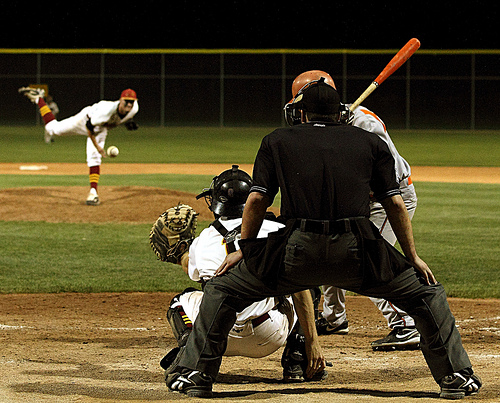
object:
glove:
[150, 202, 195, 264]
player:
[150, 164, 323, 382]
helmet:
[208, 167, 255, 218]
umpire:
[165, 369, 214, 394]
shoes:
[434, 369, 481, 400]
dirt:
[0, 289, 499, 402]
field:
[3, 124, 496, 402]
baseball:
[2, 2, 498, 399]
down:
[148, 322, 357, 395]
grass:
[2, 121, 499, 297]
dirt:
[2, 186, 281, 221]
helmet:
[280, 69, 340, 111]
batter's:
[282, 36, 424, 350]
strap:
[212, 216, 246, 254]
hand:
[302, 337, 326, 378]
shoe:
[282, 342, 331, 384]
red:
[373, 37, 420, 88]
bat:
[342, 37, 422, 125]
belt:
[289, 213, 364, 235]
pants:
[173, 215, 472, 384]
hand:
[167, 227, 194, 264]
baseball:
[108, 146, 119, 159]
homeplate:
[322, 333, 349, 356]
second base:
[20, 160, 49, 173]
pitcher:
[20, 84, 141, 204]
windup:
[81, 110, 108, 151]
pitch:
[80, 111, 126, 164]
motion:
[102, 145, 126, 158]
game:
[2, 2, 494, 402]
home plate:
[262, 313, 348, 373]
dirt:
[0, 160, 499, 186]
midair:
[109, 141, 133, 166]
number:
[360, 105, 389, 130]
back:
[344, 102, 409, 186]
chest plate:
[262, 211, 280, 224]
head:
[205, 167, 255, 220]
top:
[373, 36, 431, 89]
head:
[287, 69, 345, 113]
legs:
[325, 225, 469, 396]